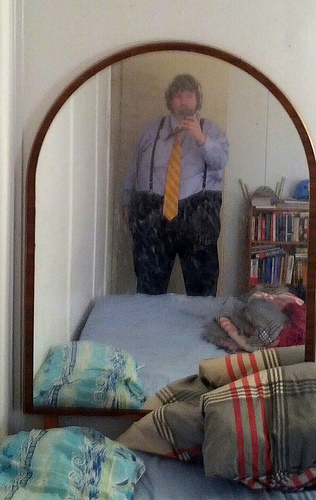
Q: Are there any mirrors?
A: Yes, there is a mirror.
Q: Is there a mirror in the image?
A: Yes, there is a mirror.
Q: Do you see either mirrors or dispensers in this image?
A: Yes, there is a mirror.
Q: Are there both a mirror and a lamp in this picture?
A: No, there is a mirror but no lamps.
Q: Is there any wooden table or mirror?
A: Yes, there is a wood mirror.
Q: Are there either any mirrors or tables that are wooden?
A: Yes, the mirror is wooden.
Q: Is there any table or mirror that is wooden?
A: Yes, the mirror is wooden.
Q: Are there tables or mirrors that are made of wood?
A: Yes, the mirror is made of wood.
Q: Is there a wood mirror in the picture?
A: Yes, there is a wood mirror.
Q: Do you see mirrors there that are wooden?
A: Yes, there is a mirror that is wooden.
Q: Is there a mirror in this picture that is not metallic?
A: Yes, there is a wooden mirror.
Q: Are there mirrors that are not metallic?
A: Yes, there is a wooden mirror.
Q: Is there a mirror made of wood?
A: Yes, there is a mirror that is made of wood.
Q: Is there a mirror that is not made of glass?
A: Yes, there is a mirror that is made of wood.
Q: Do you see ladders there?
A: No, there are no ladders.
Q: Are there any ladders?
A: No, there are no ladders.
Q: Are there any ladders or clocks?
A: No, there are no ladders or clocks.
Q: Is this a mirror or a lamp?
A: This is a mirror.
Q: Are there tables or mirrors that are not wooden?
A: No, there is a mirror but it is wooden.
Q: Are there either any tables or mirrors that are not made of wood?
A: No, there is a mirror but it is made of wood.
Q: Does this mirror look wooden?
A: Yes, the mirror is wooden.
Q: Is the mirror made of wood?
A: Yes, the mirror is made of wood.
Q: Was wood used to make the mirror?
A: Yes, the mirror is made of wood.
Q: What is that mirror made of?
A: The mirror is made of wood.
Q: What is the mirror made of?
A: The mirror is made of wood.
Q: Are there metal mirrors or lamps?
A: No, there is a mirror but it is wooden.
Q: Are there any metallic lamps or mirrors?
A: No, there is a mirror but it is wooden.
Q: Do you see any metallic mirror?
A: No, there is a mirror but it is wooden.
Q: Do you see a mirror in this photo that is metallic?
A: No, there is a mirror but it is wooden.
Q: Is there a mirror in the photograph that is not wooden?
A: No, there is a mirror but it is wooden.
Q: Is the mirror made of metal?
A: No, the mirror is made of wood.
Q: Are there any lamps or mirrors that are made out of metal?
A: No, there is a mirror but it is made of wood.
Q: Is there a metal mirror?
A: No, there is a mirror but it is made of wood.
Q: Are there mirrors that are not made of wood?
A: No, there is a mirror but it is made of wood.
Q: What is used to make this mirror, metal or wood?
A: The mirror is made of wood.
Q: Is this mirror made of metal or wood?
A: The mirror is made of wood.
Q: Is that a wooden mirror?
A: Yes, that is a wooden mirror.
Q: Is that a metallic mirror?
A: No, that is a wooden mirror.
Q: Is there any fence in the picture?
A: No, there are no fences.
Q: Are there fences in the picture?
A: No, there are no fences.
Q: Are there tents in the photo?
A: No, there are no tents.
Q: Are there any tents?
A: No, there are no tents.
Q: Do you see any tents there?
A: No, there are no tents.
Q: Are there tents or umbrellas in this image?
A: No, there are no tents or umbrellas.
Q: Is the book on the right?
A: Yes, the book is on the right of the image.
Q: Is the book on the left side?
A: No, the book is on the right of the image.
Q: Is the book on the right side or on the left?
A: The book is on the right of the image.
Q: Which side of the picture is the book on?
A: The book is on the right of the image.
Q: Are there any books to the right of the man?
A: Yes, there is a book to the right of the man.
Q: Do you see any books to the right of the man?
A: Yes, there is a book to the right of the man.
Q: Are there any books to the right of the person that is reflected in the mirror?
A: Yes, there is a book to the right of the man.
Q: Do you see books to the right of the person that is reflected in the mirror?
A: Yes, there is a book to the right of the man.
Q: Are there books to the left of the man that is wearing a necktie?
A: No, the book is to the right of the man.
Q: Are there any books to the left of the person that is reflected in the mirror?
A: No, the book is to the right of the man.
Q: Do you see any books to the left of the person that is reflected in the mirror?
A: No, the book is to the right of the man.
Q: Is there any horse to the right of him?
A: No, there is a book to the right of the man.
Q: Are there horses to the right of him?
A: No, there is a book to the right of the man.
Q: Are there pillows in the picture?
A: Yes, there is a pillow.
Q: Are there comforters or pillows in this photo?
A: Yes, there is a pillow.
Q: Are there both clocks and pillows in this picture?
A: No, there is a pillow but no clocks.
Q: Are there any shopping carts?
A: No, there are no shopping carts.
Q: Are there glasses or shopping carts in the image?
A: No, there are no shopping carts or glasses.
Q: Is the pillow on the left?
A: Yes, the pillow is on the left of the image.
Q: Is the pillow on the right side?
A: No, the pillow is on the left of the image.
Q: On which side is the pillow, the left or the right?
A: The pillow is on the left of the image.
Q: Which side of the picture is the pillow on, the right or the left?
A: The pillow is on the left of the image.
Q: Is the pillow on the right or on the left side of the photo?
A: The pillow is on the left of the image.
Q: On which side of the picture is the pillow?
A: The pillow is on the left of the image.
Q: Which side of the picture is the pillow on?
A: The pillow is on the left of the image.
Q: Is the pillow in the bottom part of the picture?
A: Yes, the pillow is in the bottom of the image.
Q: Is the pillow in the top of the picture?
A: No, the pillow is in the bottom of the image.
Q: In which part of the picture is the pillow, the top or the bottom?
A: The pillow is in the bottom of the image.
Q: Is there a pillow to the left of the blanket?
A: Yes, there is a pillow to the left of the blanket.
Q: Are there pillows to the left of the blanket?
A: Yes, there is a pillow to the left of the blanket.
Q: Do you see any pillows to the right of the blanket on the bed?
A: No, the pillow is to the left of the blanket.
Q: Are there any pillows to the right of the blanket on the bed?
A: No, the pillow is to the left of the blanket.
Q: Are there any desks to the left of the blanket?
A: No, there is a pillow to the left of the blanket.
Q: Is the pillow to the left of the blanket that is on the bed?
A: Yes, the pillow is to the left of the blanket.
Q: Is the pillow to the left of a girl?
A: No, the pillow is to the left of the blanket.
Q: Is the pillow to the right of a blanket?
A: No, the pillow is to the left of a blanket.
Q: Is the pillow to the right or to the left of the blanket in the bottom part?
A: The pillow is to the left of the blanket.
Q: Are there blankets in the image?
A: Yes, there is a blanket.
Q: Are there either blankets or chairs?
A: Yes, there is a blanket.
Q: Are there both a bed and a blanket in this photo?
A: Yes, there are both a blanket and a bed.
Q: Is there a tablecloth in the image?
A: No, there are no tablecloths.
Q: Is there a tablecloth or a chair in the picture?
A: No, there are no tablecloths or chairs.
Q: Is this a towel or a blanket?
A: This is a blanket.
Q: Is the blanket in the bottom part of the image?
A: Yes, the blanket is in the bottom of the image.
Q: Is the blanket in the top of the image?
A: No, the blanket is in the bottom of the image.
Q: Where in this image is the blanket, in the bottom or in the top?
A: The blanket is in the bottom of the image.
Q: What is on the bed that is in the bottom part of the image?
A: The blanket is on the bed.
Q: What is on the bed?
A: The blanket is on the bed.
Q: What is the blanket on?
A: The blanket is on the bed.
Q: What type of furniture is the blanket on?
A: The blanket is on the bed.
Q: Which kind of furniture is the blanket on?
A: The blanket is on the bed.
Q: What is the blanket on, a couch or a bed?
A: The blanket is on a bed.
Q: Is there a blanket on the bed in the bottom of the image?
A: Yes, there is a blanket on the bed.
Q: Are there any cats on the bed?
A: No, there is a blanket on the bed.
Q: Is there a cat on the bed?
A: No, there is a blanket on the bed.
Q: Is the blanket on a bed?
A: Yes, the blanket is on a bed.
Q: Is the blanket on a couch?
A: No, the blanket is on a bed.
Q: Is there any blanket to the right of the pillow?
A: Yes, there is a blanket to the right of the pillow.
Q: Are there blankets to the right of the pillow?
A: Yes, there is a blanket to the right of the pillow.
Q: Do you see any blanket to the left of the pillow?
A: No, the blanket is to the right of the pillow.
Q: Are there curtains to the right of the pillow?
A: No, there is a blanket to the right of the pillow.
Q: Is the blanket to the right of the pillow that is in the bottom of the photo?
A: Yes, the blanket is to the right of the pillow.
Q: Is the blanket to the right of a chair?
A: No, the blanket is to the right of the pillow.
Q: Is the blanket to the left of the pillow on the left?
A: No, the blanket is to the right of the pillow.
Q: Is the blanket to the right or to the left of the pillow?
A: The blanket is to the right of the pillow.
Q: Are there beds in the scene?
A: Yes, there is a bed.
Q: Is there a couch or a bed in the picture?
A: Yes, there is a bed.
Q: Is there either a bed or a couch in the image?
A: Yes, there is a bed.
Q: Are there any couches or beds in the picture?
A: Yes, there is a bed.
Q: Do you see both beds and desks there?
A: No, there is a bed but no desks.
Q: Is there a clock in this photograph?
A: No, there are no clocks.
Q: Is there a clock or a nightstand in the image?
A: No, there are no clocks or nightstands.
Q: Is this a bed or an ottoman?
A: This is a bed.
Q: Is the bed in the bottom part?
A: Yes, the bed is in the bottom of the image.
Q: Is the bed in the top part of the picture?
A: No, the bed is in the bottom of the image.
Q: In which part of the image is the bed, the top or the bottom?
A: The bed is in the bottom of the image.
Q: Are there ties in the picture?
A: Yes, there is a tie.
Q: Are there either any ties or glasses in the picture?
A: Yes, there is a tie.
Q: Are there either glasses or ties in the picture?
A: Yes, there is a tie.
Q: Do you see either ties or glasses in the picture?
A: Yes, there is a tie.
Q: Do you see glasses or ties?
A: Yes, there is a tie.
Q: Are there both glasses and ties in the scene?
A: No, there is a tie but no glasses.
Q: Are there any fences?
A: No, there are no fences.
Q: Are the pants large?
A: Yes, the pants are large.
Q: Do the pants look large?
A: Yes, the pants are large.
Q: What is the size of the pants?
A: The pants are large.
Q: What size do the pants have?
A: The pants have large size.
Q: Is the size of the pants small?
A: No, the pants are large.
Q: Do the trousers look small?
A: No, the trousers are large.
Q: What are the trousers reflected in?
A: The trousers are reflected in the mirror.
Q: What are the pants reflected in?
A: The trousers are reflected in the mirror.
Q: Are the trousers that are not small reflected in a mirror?
A: Yes, the pants are reflected in a mirror.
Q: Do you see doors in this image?
A: Yes, there is a door.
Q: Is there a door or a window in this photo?
A: Yes, there is a door.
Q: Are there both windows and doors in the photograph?
A: No, there is a door but no windows.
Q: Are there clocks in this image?
A: No, there are no clocks.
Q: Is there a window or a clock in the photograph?
A: No, there are no clocks or windows.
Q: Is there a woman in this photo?
A: No, there are no women.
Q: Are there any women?
A: No, there are no women.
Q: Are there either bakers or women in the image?
A: No, there are no women or bakers.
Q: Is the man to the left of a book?
A: Yes, the man is to the left of a book.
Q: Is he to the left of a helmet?
A: No, the man is to the left of a book.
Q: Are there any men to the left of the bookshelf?
A: Yes, there is a man to the left of the bookshelf.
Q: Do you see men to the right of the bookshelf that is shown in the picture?
A: No, the man is to the left of the bookshelf.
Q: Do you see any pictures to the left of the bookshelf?
A: No, there is a man to the left of the bookshelf.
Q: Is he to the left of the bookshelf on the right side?
A: Yes, the man is to the left of the bookshelf.